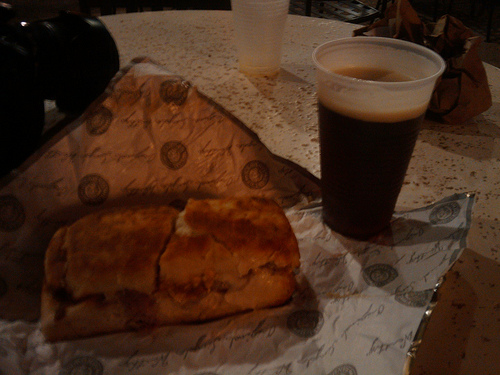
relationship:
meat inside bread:
[64, 260, 276, 325] [31, 192, 300, 337]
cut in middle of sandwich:
[148, 198, 201, 322] [37, 201, 304, 334]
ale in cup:
[314, 94, 425, 242] [310, 34, 446, 244]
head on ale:
[322, 62, 435, 127] [314, 94, 425, 242]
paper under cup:
[4, 57, 483, 375] [310, 34, 446, 244]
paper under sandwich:
[4, 57, 483, 375] [37, 201, 304, 334]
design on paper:
[54, 81, 276, 197] [4, 57, 483, 375]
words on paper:
[363, 326, 414, 361] [4, 57, 483, 375]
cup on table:
[235, 0, 282, 73] [2, 7, 499, 374]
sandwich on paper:
[37, 201, 304, 334] [4, 57, 483, 375]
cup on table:
[310, 34, 446, 244] [2, 7, 499, 374]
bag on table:
[361, 1, 500, 121] [2, 7, 499, 374]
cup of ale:
[310, 34, 446, 244] [314, 94, 425, 242]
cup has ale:
[310, 34, 446, 244] [314, 94, 425, 242]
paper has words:
[4, 57, 483, 375] [363, 326, 414, 361]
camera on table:
[0, 6, 117, 143] [2, 7, 499, 374]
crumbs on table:
[243, 76, 322, 160] [2, 7, 499, 374]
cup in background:
[235, 0, 282, 73] [0, 2, 500, 96]